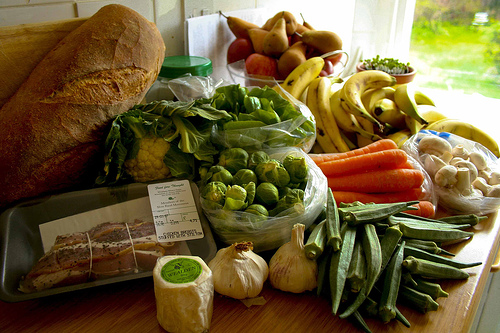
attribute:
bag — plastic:
[396, 122, 484, 204]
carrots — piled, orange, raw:
[315, 136, 433, 214]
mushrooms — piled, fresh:
[415, 129, 498, 198]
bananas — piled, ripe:
[275, 53, 497, 158]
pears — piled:
[215, 5, 352, 88]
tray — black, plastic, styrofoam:
[7, 179, 223, 299]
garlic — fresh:
[209, 241, 272, 295]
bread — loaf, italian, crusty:
[0, 5, 165, 208]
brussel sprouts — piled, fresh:
[200, 143, 327, 243]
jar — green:
[162, 55, 215, 75]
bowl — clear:
[230, 65, 353, 96]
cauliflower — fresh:
[102, 107, 189, 184]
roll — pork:
[21, 215, 175, 284]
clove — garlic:
[270, 224, 324, 297]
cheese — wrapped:
[150, 251, 218, 330]